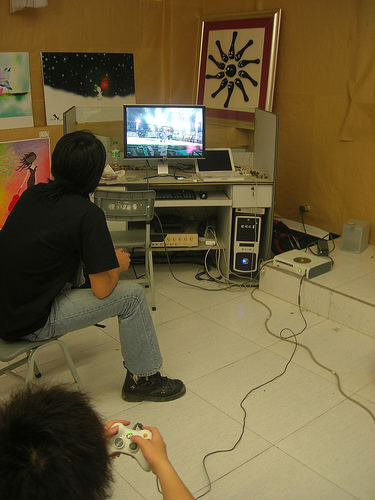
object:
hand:
[99, 419, 130, 437]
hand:
[129, 425, 166, 473]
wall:
[1, 1, 371, 245]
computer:
[121, 101, 206, 185]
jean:
[29, 275, 173, 376]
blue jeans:
[21, 282, 163, 374]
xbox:
[272, 246, 333, 277]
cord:
[132, 262, 311, 497]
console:
[272, 249, 336, 280]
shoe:
[120, 370, 186, 404]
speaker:
[341, 218, 371, 253]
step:
[258, 233, 374, 338]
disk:
[275, 249, 333, 270]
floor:
[191, 298, 313, 456]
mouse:
[199, 191, 207, 200]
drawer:
[154, 189, 232, 207]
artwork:
[194, 7, 282, 130]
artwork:
[40, 51, 136, 125]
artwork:
[0, 50, 34, 128]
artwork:
[0, 136, 53, 230]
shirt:
[0, 181, 119, 344]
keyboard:
[136, 188, 197, 202]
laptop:
[193, 147, 245, 182]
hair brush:
[1, 372, 104, 407]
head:
[2, 382, 112, 499]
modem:
[232, 214, 261, 276]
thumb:
[116, 247, 124, 256]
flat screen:
[122, 101, 206, 167]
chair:
[90, 188, 163, 311]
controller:
[103, 422, 159, 474]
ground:
[168, 338, 346, 488]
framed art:
[193, 10, 281, 131]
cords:
[197, 221, 261, 294]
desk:
[56, 101, 284, 283]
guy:
[0, 371, 201, 499]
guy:
[0, 125, 188, 404]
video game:
[124, 103, 207, 158]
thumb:
[129, 435, 147, 447]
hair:
[0, 375, 121, 499]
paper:
[272, 4, 372, 228]